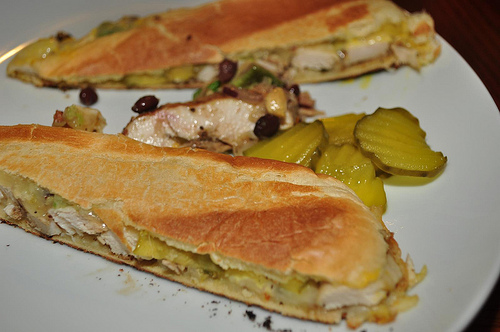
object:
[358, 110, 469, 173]
chips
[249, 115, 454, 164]
pickle slices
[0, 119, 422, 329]
sandwich half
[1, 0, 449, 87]
sandwich half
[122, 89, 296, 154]
chicken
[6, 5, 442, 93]
sandwich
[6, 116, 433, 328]
sandwich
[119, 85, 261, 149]
meat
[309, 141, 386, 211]
pickle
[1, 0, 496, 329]
plate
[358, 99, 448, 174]
slices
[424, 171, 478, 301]
plate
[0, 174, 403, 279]
food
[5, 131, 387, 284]
bread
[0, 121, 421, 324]
piece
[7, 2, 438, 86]
piece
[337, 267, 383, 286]
cheese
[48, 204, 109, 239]
chicken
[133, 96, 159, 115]
caper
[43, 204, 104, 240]
meat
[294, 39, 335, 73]
meat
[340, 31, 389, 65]
meat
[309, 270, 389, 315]
meat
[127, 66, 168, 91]
pickles